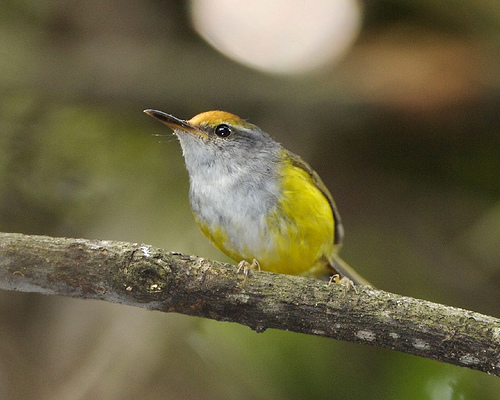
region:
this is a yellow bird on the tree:
[60, 90, 397, 368]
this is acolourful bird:
[130, 105, 422, 397]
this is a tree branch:
[68, 216, 385, 379]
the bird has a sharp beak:
[157, 106, 211, 143]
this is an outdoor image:
[64, 141, 394, 338]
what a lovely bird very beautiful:
[78, 126, 483, 372]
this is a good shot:
[147, 31, 397, 102]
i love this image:
[51, 60, 471, 371]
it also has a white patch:
[151, 146, 281, 261]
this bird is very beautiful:
[68, 132, 476, 295]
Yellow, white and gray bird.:
[139, 110, 375, 290]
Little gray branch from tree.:
[0, 234, 498, 387]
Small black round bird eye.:
[213, 124, 231, 139]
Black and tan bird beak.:
[139, 105, 204, 137]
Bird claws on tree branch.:
[235, 257, 359, 295]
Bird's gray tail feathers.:
[322, 253, 374, 290]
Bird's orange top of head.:
[185, 110, 250, 124]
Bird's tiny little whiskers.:
[142, 133, 178, 143]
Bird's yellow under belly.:
[268, 164, 335, 278]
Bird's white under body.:
[178, 129, 278, 249]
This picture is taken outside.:
[0, 19, 490, 394]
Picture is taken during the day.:
[22, 7, 493, 398]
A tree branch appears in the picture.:
[2, 263, 491, 381]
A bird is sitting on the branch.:
[123, 103, 400, 303]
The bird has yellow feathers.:
[150, 87, 349, 294]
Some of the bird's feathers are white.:
[182, 120, 288, 247]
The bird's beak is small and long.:
[134, 77, 209, 181]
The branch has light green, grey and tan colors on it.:
[11, 232, 446, 362]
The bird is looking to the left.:
[124, 60, 486, 342]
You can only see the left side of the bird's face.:
[168, 124, 345, 231]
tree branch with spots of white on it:
[7, 235, 497, 379]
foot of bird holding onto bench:
[229, 260, 268, 277]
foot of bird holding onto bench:
[331, 275, 361, 297]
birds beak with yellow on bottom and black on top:
[137, 110, 193, 132]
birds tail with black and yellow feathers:
[334, 256, 365, 287]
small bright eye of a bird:
[214, 122, 234, 139]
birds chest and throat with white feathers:
[179, 133, 281, 261]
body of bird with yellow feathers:
[203, 170, 328, 277]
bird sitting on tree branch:
[141, 102, 362, 289]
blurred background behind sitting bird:
[5, 0, 498, 395]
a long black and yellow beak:
[135, 103, 196, 145]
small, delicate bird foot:
[231, 248, 266, 283]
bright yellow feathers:
[286, 189, 331, 259]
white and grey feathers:
[207, 151, 259, 216]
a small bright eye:
[213, 121, 234, 143]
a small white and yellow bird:
[138, 89, 365, 291]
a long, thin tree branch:
[33, 224, 470, 376]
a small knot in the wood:
[114, 251, 189, 304]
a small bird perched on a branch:
[30, 94, 475, 362]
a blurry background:
[308, 24, 479, 181]